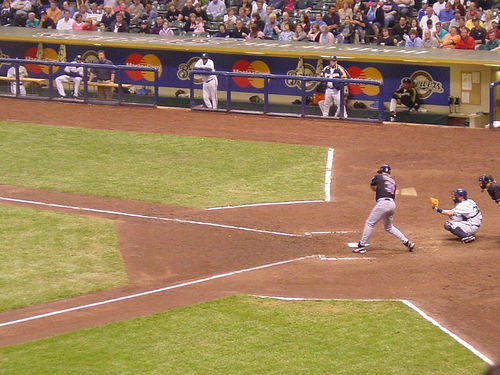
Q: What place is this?
A: It is a field.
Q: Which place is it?
A: It is a field.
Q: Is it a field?
A: Yes, it is a field.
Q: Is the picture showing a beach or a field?
A: It is showing a field.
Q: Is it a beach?
A: No, it is a field.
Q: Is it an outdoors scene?
A: Yes, it is outdoors.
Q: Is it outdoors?
A: Yes, it is outdoors.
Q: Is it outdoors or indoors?
A: It is outdoors.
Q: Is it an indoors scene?
A: No, it is outdoors.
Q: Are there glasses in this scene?
A: No, there are no glasses.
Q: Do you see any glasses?
A: No, there are no glasses.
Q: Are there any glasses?
A: No, there are no glasses.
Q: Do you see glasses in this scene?
A: No, there are no glasses.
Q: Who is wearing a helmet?
A: The man is wearing a helmet.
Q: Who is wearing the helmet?
A: The man is wearing a helmet.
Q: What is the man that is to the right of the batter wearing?
A: The man is wearing a helmet.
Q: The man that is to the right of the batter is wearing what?
A: The man is wearing a helmet.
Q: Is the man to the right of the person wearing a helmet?
A: Yes, the man is wearing a helmet.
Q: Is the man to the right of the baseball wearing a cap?
A: No, the man is wearing a helmet.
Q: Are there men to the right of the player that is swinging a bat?
A: Yes, there is a man to the right of the player.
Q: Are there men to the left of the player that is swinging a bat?
A: No, the man is to the right of the player.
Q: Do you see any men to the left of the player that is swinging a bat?
A: No, the man is to the right of the player.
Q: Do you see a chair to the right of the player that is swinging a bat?
A: No, there is a man to the right of the player.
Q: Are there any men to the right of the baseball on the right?
A: Yes, there is a man to the right of the baseball.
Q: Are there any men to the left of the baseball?
A: No, the man is to the right of the baseball.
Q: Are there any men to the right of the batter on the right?
A: Yes, there is a man to the right of the batter.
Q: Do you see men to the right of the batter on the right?
A: Yes, there is a man to the right of the batter.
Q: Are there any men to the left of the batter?
A: No, the man is to the right of the batter.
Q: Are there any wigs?
A: No, there are no wigs.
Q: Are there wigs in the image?
A: No, there are no wigs.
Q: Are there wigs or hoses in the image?
A: No, there are no wigs or hoses.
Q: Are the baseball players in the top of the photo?
A: Yes, the baseball players are in the top of the image.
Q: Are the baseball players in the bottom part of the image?
A: No, the baseball players are in the top of the image.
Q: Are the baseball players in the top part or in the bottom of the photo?
A: The baseball players are in the top of the image.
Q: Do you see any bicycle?
A: No, there are no bicycles.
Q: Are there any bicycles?
A: No, there are no bicycles.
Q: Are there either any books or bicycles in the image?
A: No, there are no bicycles or books.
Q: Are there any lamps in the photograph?
A: No, there are no lamps.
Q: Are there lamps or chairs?
A: No, there are no lamps or chairs.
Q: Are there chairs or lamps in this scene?
A: No, there are no lamps or chairs.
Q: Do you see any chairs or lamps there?
A: No, there are no lamps or chairs.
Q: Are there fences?
A: Yes, there is a fence.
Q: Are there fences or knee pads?
A: Yes, there is a fence.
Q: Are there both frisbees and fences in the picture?
A: No, there is a fence but no frisbees.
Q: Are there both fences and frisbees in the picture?
A: No, there is a fence but no frisbees.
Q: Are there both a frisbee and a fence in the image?
A: No, there is a fence but no frisbees.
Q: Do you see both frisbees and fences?
A: No, there is a fence but no frisbees.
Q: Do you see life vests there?
A: No, there are no life vests.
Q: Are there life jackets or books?
A: No, there are no life jackets or books.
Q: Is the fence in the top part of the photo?
A: Yes, the fence is in the top of the image.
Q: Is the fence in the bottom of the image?
A: No, the fence is in the top of the image.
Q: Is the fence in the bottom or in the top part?
A: The fence is in the top of the image.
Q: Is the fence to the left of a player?
A: Yes, the fence is to the left of a player.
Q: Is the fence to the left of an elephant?
A: No, the fence is to the left of a player.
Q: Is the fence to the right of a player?
A: No, the fence is to the left of a player.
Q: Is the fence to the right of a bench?
A: No, the fence is to the left of a bench.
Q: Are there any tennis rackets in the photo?
A: No, there are no tennis rackets.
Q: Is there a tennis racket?
A: No, there are no rackets.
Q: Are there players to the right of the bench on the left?
A: Yes, there is a player to the right of the bench.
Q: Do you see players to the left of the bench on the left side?
A: No, the player is to the right of the bench.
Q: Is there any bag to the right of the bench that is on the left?
A: No, there is a player to the right of the bench.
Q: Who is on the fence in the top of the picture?
A: The player is on the fence.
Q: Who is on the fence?
A: The player is on the fence.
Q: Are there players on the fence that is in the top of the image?
A: Yes, there is a player on the fence.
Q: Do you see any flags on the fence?
A: No, there is a player on the fence.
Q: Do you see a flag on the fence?
A: No, there is a player on the fence.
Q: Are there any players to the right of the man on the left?
A: Yes, there is a player to the right of the man.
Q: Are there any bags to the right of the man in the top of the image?
A: No, there is a player to the right of the man.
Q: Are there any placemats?
A: No, there are no placemats.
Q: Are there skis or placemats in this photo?
A: No, there are no placemats or skis.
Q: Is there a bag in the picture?
A: No, there are no bags.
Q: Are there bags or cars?
A: No, there are no bags or cars.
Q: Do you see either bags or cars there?
A: No, there are no bags or cars.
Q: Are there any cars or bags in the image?
A: No, there are no bags or cars.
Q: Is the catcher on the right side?
A: Yes, the catcher is on the right of the image.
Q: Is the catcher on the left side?
A: No, the catcher is on the right of the image.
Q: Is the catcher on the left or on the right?
A: The catcher is on the right of the image.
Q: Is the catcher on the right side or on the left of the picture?
A: The catcher is on the right of the image.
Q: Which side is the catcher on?
A: The catcher is on the right of the image.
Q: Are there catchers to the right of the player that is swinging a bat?
A: Yes, there is a catcher to the right of the player.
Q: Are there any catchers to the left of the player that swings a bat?
A: No, the catcher is to the right of the player.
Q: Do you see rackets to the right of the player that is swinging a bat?
A: No, there is a catcher to the right of the player.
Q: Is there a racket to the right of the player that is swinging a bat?
A: No, there is a catcher to the right of the player.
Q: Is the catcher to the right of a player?
A: Yes, the catcher is to the right of a player.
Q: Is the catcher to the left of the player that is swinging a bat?
A: No, the catcher is to the right of the player.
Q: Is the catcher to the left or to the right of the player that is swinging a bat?
A: The catcher is to the right of the player.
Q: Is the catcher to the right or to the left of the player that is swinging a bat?
A: The catcher is to the right of the player.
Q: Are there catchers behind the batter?
A: Yes, there is a catcher behind the batter.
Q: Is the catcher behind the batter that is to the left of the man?
A: Yes, the catcher is behind the batter.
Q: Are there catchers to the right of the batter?
A: Yes, there is a catcher to the right of the batter.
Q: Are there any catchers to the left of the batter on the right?
A: No, the catcher is to the right of the batter.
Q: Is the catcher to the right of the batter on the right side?
A: Yes, the catcher is to the right of the batter.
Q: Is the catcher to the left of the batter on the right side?
A: No, the catcher is to the right of the batter.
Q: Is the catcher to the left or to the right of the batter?
A: The catcher is to the right of the batter.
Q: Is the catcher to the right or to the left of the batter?
A: The catcher is to the right of the batter.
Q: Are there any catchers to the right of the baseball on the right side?
A: Yes, there is a catcher to the right of the baseball.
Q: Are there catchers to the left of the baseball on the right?
A: No, the catcher is to the right of the baseball.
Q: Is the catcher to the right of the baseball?
A: Yes, the catcher is to the right of the baseball.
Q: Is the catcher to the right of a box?
A: No, the catcher is to the right of the baseball.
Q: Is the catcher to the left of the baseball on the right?
A: No, the catcher is to the right of the baseball.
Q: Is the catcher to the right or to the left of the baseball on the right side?
A: The catcher is to the right of the baseball.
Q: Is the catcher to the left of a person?
A: No, the catcher is to the right of a person.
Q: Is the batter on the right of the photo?
A: Yes, the batter is on the right of the image.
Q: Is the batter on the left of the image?
A: No, the batter is on the right of the image.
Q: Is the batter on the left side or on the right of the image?
A: The batter is on the right of the image.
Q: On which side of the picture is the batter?
A: The batter is on the right of the image.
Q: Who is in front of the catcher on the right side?
A: The batter is in front of the catcher.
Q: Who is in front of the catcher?
A: The batter is in front of the catcher.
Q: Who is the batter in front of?
A: The batter is in front of the catcher.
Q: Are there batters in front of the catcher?
A: Yes, there is a batter in front of the catcher.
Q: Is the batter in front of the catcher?
A: Yes, the batter is in front of the catcher.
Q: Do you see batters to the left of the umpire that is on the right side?
A: Yes, there is a batter to the left of the umpire.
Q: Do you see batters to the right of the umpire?
A: No, the batter is to the left of the umpire.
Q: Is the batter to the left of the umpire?
A: Yes, the batter is to the left of the umpire.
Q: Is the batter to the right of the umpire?
A: No, the batter is to the left of the umpire.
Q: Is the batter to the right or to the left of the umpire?
A: The batter is to the left of the umpire.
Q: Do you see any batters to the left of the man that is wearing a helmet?
A: Yes, there is a batter to the left of the man.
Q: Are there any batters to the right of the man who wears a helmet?
A: No, the batter is to the left of the man.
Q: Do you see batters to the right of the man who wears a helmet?
A: No, the batter is to the left of the man.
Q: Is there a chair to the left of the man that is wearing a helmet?
A: No, there is a batter to the left of the man.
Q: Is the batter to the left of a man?
A: Yes, the batter is to the left of a man.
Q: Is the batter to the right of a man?
A: No, the batter is to the left of a man.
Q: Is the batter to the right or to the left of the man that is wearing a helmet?
A: The batter is to the left of the man.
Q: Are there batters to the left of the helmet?
A: Yes, there is a batter to the left of the helmet.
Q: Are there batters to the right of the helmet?
A: No, the batter is to the left of the helmet.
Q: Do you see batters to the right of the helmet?
A: No, the batter is to the left of the helmet.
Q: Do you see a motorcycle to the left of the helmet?
A: No, there is a batter to the left of the helmet.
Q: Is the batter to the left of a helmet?
A: Yes, the batter is to the left of a helmet.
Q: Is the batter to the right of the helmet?
A: No, the batter is to the left of the helmet.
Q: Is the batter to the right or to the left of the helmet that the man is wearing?
A: The batter is to the left of the helmet.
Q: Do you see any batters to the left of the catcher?
A: Yes, there is a batter to the left of the catcher.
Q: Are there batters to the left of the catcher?
A: Yes, there is a batter to the left of the catcher.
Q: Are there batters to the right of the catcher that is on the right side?
A: No, the batter is to the left of the catcher.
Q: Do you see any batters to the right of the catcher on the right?
A: No, the batter is to the left of the catcher.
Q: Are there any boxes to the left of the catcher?
A: No, there is a batter to the left of the catcher.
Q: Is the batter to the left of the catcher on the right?
A: Yes, the batter is to the left of the catcher.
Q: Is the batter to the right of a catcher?
A: No, the batter is to the left of a catcher.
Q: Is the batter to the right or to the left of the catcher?
A: The batter is to the left of the catcher.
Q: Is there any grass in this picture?
A: Yes, there is grass.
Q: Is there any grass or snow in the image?
A: Yes, there is grass.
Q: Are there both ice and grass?
A: No, there is grass but no ice.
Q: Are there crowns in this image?
A: No, there are no crowns.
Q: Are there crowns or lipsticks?
A: No, there are no crowns or lipsticks.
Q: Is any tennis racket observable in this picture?
A: No, there are no rackets.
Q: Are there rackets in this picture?
A: No, there are no rackets.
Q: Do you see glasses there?
A: No, there are no glasses.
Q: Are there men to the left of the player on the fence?
A: Yes, there is a man to the left of the player.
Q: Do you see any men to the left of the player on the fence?
A: Yes, there is a man to the left of the player.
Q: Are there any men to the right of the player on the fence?
A: No, the man is to the left of the player.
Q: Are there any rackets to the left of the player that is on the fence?
A: No, there is a man to the left of the player.